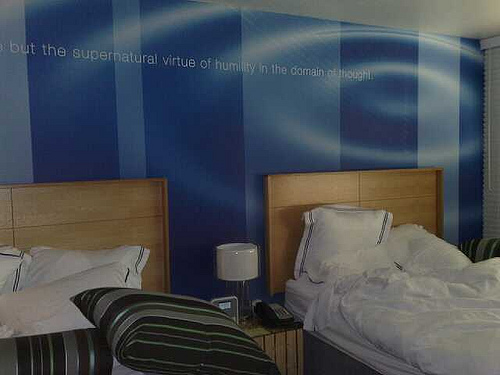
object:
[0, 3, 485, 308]
wall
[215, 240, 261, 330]
lamp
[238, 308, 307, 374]
nightstand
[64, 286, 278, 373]
pillow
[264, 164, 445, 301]
board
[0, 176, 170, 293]
board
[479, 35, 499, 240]
blinds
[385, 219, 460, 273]
pillow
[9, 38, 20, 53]
words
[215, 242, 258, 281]
shade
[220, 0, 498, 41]
ceiling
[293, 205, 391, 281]
pillow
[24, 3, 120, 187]
stripe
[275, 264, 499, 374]
cot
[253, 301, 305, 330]
phone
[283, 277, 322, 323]
mattress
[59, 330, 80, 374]
stripes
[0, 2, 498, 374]
scene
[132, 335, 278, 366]
stripe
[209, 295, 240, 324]
radio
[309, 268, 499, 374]
comforter